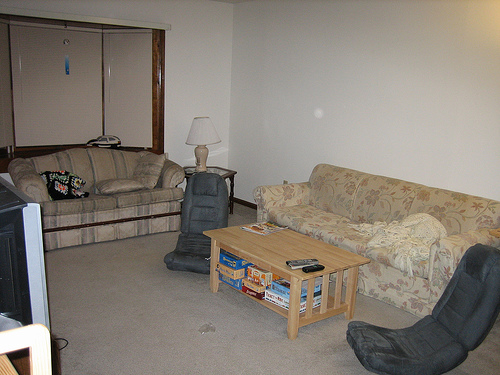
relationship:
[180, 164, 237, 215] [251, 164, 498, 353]
small table between floral couch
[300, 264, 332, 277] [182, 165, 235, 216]
tv remote on wood table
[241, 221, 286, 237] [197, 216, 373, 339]
magazine on table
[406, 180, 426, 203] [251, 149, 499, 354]
prints on floral couch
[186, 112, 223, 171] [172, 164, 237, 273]
lamp on table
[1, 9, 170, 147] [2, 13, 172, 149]
couch front window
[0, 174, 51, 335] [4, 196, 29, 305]
black tv has side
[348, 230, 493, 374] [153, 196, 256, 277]
black chair by coffe table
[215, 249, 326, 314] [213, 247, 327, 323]
board games in bunch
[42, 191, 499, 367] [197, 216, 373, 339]
carpet front table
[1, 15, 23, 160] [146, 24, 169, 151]
window on side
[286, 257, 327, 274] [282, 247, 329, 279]
remotes on table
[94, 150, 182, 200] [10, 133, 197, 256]
pillows on couch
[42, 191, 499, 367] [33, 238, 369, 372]
carpet on ground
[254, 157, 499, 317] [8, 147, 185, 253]
tan couch flowered couch couch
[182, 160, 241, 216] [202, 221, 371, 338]
wood table glass table coffe table